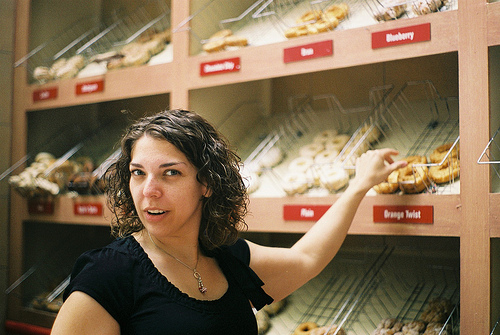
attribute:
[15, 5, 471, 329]
shelves — wooden